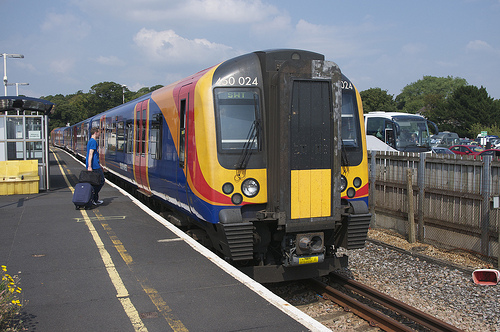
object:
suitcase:
[72, 170, 102, 211]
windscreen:
[212, 78, 363, 151]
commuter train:
[50, 47, 375, 285]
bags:
[71, 169, 105, 209]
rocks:
[458, 288, 500, 331]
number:
[214, 77, 259, 86]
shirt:
[85, 137, 101, 169]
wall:
[0, 124, 48, 159]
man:
[85, 126, 106, 207]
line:
[154, 211, 260, 303]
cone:
[471, 269, 499, 286]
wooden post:
[404, 166, 419, 243]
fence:
[365, 148, 500, 260]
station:
[5, 25, 387, 330]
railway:
[310, 272, 466, 332]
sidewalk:
[0, 145, 330, 331]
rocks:
[392, 243, 445, 298]